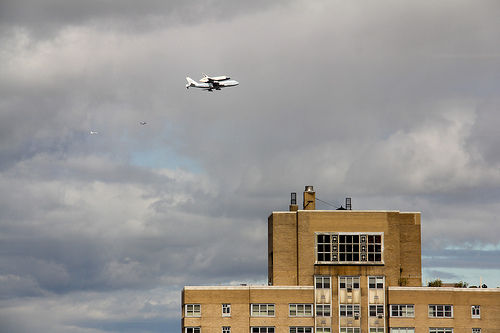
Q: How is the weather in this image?
A: It is cloudy.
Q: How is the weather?
A: It is cloudy.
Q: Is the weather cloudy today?
A: Yes, it is cloudy.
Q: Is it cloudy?
A: Yes, it is cloudy.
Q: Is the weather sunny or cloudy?
A: It is cloudy.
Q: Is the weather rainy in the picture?
A: No, it is cloudy.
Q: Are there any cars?
A: No, there are no cars.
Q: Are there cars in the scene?
A: No, there are no cars.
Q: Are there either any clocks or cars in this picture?
A: No, there are no cars or clocks.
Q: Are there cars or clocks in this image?
A: No, there are no cars or clocks.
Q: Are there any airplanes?
A: Yes, there is an airplane.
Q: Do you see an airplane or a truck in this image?
A: Yes, there is an airplane.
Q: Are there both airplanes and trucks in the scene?
A: No, there is an airplane but no trucks.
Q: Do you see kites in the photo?
A: No, there are no kites.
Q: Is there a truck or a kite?
A: No, there are no kites or trucks.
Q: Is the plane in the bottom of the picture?
A: No, the plane is in the top of the image.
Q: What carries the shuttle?
A: The airplane carries the shuttle.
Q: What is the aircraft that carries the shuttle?
A: The aircraft is an airplane.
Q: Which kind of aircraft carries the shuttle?
A: The aircraft is an airplane.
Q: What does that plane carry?
A: The plane carries a shuttle.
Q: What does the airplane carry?
A: The plane carries a shuttle.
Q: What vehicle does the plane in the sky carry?
A: The plane carries a shuttle.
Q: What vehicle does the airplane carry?
A: The plane carries a shuttle.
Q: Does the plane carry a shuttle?
A: Yes, the plane carries a shuttle.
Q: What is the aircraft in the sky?
A: The aircraft is an airplane.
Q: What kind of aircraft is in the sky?
A: The aircraft is an airplane.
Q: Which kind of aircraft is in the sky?
A: The aircraft is an airplane.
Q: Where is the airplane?
A: The airplane is in the sky.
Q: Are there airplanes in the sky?
A: Yes, there is an airplane in the sky.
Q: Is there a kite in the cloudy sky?
A: No, there is an airplane in the sky.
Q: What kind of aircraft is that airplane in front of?
A: The airplane is in front of the jet.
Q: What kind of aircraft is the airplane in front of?
A: The airplane is in front of the jet.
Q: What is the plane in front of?
A: The plane is in front of the jet.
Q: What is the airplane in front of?
A: The plane is in front of the jet.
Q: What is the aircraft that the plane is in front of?
A: The aircraft is a jet.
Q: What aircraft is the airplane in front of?
A: The plane is in front of the jet.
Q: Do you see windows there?
A: Yes, there are windows.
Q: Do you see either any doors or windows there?
A: Yes, there are windows.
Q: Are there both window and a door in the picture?
A: No, there are windows but no doors.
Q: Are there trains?
A: No, there are no trains.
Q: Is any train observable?
A: No, there are no trains.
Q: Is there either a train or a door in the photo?
A: No, there are no trains or doors.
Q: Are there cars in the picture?
A: No, there are no cars.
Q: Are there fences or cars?
A: No, there are no cars or fences.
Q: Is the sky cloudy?
A: Yes, the sky is cloudy.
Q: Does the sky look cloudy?
A: Yes, the sky is cloudy.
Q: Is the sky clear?
A: No, the sky is cloudy.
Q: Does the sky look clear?
A: No, the sky is cloudy.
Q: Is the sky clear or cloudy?
A: The sky is cloudy.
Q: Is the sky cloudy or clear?
A: The sky is cloudy.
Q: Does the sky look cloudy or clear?
A: The sky is cloudy.